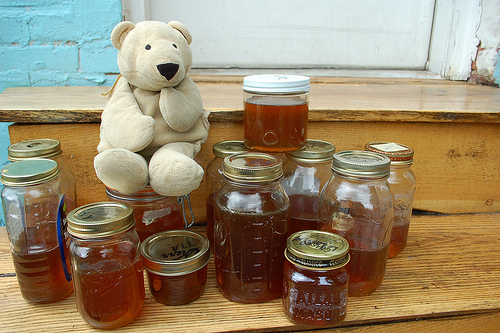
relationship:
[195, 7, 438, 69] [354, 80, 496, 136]
door on to of steps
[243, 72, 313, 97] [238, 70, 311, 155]
lid on jar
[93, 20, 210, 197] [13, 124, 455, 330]
bear on jars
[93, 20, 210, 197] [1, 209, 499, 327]
bear on counter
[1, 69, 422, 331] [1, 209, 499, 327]
bottles on counter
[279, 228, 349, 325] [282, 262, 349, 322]
jar filled with liquid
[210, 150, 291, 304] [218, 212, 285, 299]
jar filled with liquid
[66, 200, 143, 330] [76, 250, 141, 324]
jar filled with liquid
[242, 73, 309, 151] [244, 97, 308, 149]
jar filled with liquid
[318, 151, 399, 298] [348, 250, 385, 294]
jar filled with liquid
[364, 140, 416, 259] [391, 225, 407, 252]
jar filled with liquid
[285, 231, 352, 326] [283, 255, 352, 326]
pint jar filled with honey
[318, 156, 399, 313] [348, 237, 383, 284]
jar filled with honey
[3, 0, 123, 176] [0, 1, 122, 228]
paint on brick wall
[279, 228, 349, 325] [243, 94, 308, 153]
jar has honey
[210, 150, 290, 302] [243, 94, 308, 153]
jar has honey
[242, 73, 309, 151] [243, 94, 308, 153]
jar has honey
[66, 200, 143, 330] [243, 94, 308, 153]
jar has honey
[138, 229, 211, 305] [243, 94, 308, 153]
jar has honey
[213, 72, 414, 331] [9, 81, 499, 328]
honey on counter